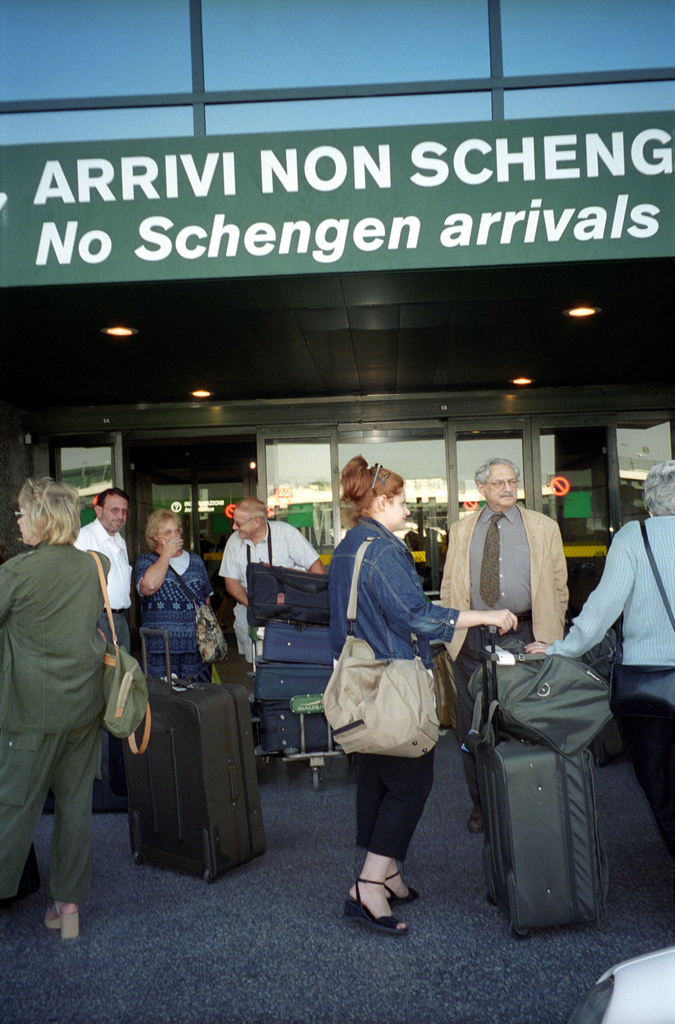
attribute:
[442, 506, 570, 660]
jacket — tan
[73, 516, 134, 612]
shirt — white, button-up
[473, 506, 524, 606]
tie — short ugly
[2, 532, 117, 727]
top — olive green 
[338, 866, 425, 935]
sandals — black wedge , pair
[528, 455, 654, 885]
woman — older 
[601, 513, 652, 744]
purse — black  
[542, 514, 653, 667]
sweater — blue 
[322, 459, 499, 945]
woman — red haired 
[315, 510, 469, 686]
jacket — jean 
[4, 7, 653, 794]
building — side 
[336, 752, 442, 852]
pants — black 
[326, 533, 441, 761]
bag — brown 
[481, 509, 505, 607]
tie — brown 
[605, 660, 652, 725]
purse — black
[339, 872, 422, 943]
shoes — black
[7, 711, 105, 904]
pants — green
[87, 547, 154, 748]
bag — green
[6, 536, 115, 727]
jacket — green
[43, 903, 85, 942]
shoes — brown 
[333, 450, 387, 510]
hair — long red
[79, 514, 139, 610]
shirt — white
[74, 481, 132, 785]
man — old 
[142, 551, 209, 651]
shirt — blue  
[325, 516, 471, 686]
jacket — jean 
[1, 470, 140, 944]
woman — dark green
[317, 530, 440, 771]
bag — tan 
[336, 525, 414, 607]
shoulder — woman's 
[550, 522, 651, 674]
jacket — gray 